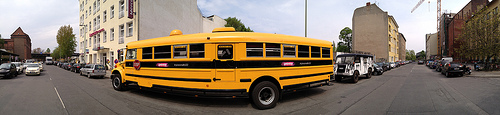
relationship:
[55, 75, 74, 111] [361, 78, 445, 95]
stripe on road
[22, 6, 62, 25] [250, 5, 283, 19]
clouds in sky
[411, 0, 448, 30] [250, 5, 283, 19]
crane in sky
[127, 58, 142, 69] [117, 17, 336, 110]
stop sign on bus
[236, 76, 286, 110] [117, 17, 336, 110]
tire on bus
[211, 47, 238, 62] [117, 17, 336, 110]
window on bus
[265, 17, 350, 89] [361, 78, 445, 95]
bus on road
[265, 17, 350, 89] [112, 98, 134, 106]
bus on street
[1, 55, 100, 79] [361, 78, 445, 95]
cars on road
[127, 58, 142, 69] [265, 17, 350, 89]
stop sign on bus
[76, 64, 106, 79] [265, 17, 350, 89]
minivan of bus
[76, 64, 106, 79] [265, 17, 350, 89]
minivan on bus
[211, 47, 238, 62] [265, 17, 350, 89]
window on bus